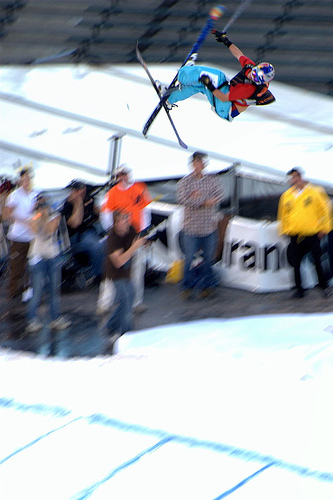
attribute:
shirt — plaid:
[174, 173, 222, 237]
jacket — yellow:
[278, 185, 331, 238]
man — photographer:
[104, 213, 155, 338]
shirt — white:
[7, 188, 33, 243]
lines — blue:
[1, 396, 333, 499]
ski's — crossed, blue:
[135, 3, 227, 149]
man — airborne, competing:
[166, 30, 276, 120]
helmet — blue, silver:
[250, 61, 277, 86]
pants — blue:
[166, 64, 230, 119]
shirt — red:
[228, 57, 257, 112]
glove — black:
[213, 29, 231, 46]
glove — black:
[198, 75, 213, 91]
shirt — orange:
[109, 184, 144, 233]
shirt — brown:
[105, 227, 134, 277]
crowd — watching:
[0, 153, 329, 333]